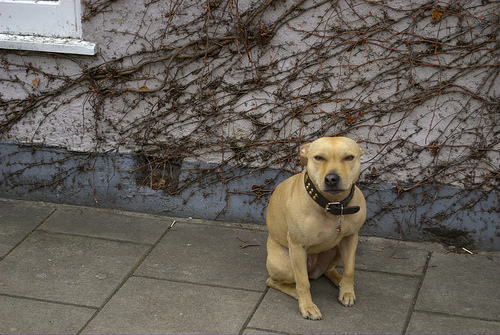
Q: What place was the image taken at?
A: It was taken at the sidewalk.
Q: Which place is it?
A: It is a sidewalk.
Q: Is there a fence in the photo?
A: No, there are no fences.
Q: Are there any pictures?
A: No, there are no pictures.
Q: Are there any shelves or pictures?
A: No, there are no pictures or shelves.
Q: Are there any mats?
A: No, there are no mats.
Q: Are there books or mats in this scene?
A: No, there are no mats or books.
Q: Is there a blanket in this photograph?
A: No, there are no blankets.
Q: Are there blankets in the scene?
A: No, there are no blankets.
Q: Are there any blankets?
A: No, there are no blankets.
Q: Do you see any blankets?
A: No, there are no blankets.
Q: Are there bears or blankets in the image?
A: No, there are no blankets or bears.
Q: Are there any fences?
A: No, there are no fences.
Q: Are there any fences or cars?
A: No, there are no fences or cars.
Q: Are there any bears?
A: No, there are no bears.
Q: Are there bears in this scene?
A: No, there are no bears.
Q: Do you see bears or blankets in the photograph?
A: No, there are no bears or blankets.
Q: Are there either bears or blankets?
A: No, there are no bears or blankets.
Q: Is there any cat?
A: No, there are no cats.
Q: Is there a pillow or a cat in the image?
A: No, there are no cats or pillows.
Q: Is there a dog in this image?
A: Yes, there is a dog.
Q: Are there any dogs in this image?
A: Yes, there is a dog.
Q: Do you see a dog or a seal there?
A: Yes, there is a dog.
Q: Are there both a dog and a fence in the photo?
A: No, there is a dog but no fences.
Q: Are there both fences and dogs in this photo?
A: No, there is a dog but no fences.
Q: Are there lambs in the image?
A: No, there are no lambs.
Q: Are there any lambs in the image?
A: No, there are no lambs.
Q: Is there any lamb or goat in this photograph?
A: No, there are no lambs or goats.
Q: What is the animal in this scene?
A: The animal is a dog.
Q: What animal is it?
A: The animal is a dog.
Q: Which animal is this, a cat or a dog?
A: That is a dog.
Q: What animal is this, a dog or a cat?
A: That is a dog.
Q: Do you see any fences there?
A: No, there are no fences.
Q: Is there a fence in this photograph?
A: No, there are no fences.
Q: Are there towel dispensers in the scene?
A: No, there are no towel dispensers.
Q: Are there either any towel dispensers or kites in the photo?
A: No, there are no towel dispensers or kites.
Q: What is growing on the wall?
A: The vines are growing on the wall.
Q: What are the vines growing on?
A: The vines are growing on the wall.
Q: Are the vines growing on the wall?
A: Yes, the vines are growing on the wall.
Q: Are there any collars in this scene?
A: Yes, there is a collar.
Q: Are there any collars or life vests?
A: Yes, there is a collar.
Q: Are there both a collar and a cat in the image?
A: No, there is a collar but no cats.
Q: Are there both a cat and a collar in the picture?
A: No, there is a collar but no cats.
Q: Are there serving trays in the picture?
A: No, there are no serving trays.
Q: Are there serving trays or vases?
A: No, there are no serving trays or vases.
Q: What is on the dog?
A: The collar is on the dog.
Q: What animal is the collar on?
A: The collar is on the dog.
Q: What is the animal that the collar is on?
A: The animal is a dog.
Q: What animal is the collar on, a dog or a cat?
A: The collar is on a dog.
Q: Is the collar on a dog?
A: Yes, the collar is on a dog.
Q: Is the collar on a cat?
A: No, the collar is on a dog.